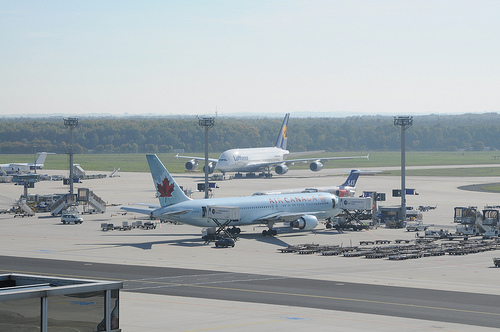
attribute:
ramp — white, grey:
[213, 214, 227, 230]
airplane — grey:
[94, 127, 399, 259]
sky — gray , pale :
[367, 20, 449, 71]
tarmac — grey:
[3, 230, 490, 329]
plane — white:
[87, 140, 417, 256]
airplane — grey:
[119, 151, 343, 234]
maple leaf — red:
[154, 173, 176, 198]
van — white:
[62, 209, 84, 224]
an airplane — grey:
[143, 138, 415, 249]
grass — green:
[414, 167, 497, 176]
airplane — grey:
[176, 166, 340, 237]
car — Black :
[214, 240, 243, 252]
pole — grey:
[393, 113, 413, 226]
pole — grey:
[194, 114, 215, 197]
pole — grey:
[65, 118, 75, 195]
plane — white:
[121, 152, 366, 248]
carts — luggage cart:
[101, 215, 159, 234]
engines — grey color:
[274, 159, 325, 172]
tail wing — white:
[146, 150, 194, 203]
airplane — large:
[173, 113, 370, 176]